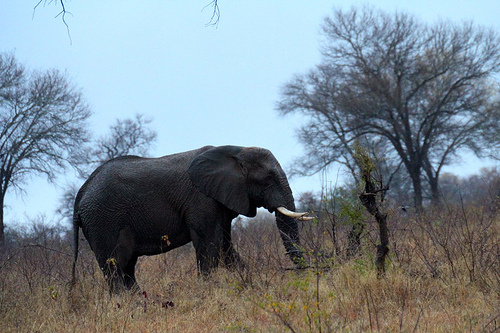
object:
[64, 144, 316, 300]
elephant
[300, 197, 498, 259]
brush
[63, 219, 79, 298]
tail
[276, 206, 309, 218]
tusks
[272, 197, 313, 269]
trunk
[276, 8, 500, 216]
trees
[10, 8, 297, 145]
sky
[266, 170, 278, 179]
eye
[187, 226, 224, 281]
legs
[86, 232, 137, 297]
legs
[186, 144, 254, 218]
ears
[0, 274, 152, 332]
grass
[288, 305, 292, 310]
flowers